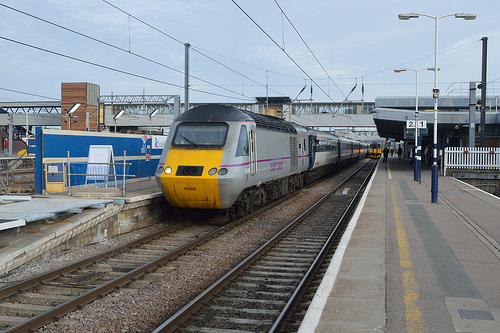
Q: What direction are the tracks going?
A: Parallel.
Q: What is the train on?
A: Rusted tracks.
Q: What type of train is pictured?
A: Electric.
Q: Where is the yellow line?
A: Platform.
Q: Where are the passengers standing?
A: Platform.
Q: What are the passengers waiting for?
A: Train.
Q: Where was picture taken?
A: Train station.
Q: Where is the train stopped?
A: Station.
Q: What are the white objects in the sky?
A: Clouds.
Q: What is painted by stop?
A: Yellow line.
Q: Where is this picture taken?
A: Train station.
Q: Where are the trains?
A: On the tracks.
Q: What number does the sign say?
A: 21.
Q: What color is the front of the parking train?
A: Yellow.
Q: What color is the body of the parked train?
A: Silver.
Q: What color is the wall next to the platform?
A: Blue.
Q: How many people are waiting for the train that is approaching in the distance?
A: Three.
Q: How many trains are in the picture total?
A: Two.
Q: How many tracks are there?
A: Two.